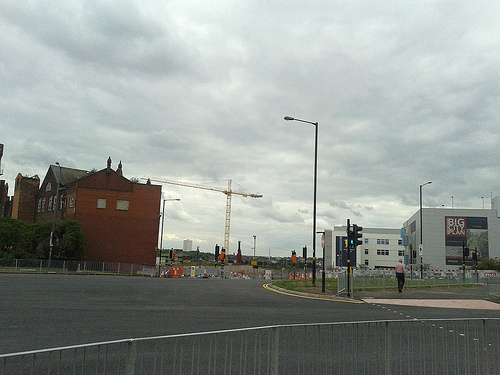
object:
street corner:
[264, 270, 499, 312]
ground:
[416, 109, 443, 141]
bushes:
[0, 218, 86, 271]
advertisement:
[443, 215, 490, 266]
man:
[393, 258, 408, 293]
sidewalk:
[6, 271, 498, 369]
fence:
[0, 259, 164, 277]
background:
[0, 4, 499, 374]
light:
[283, 115, 295, 121]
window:
[114, 198, 131, 211]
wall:
[71, 183, 161, 267]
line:
[260, 281, 365, 305]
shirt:
[393, 261, 405, 274]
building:
[0, 156, 163, 274]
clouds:
[197, 36, 407, 96]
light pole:
[311, 121, 318, 286]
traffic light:
[346, 218, 364, 301]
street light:
[283, 115, 319, 286]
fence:
[0, 316, 499, 374]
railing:
[0, 318, 499, 373]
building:
[324, 187, 498, 279]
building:
[182, 238, 194, 252]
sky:
[357, 26, 455, 62]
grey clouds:
[34, 13, 90, 44]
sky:
[0, 1, 115, 92]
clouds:
[388, 3, 498, 75]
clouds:
[389, 102, 489, 189]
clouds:
[60, 7, 175, 67]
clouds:
[131, 107, 269, 189]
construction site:
[157, 248, 323, 268]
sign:
[285, 249, 297, 266]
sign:
[250, 255, 258, 270]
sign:
[217, 248, 225, 263]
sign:
[166, 248, 176, 260]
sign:
[162, 265, 184, 277]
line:
[370, 300, 493, 349]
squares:
[117, 197, 130, 211]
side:
[75, 183, 162, 272]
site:
[181, 228, 471, 293]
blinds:
[96, 196, 108, 211]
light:
[348, 238, 356, 244]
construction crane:
[139, 175, 263, 263]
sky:
[128, 73, 295, 161]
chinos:
[395, 272, 406, 289]